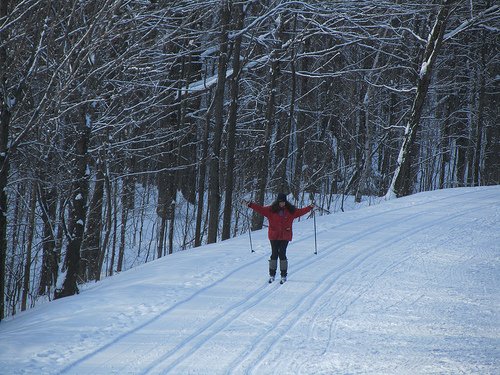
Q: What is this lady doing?
A: Skiing.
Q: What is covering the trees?
A: Snow.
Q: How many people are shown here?
A: One.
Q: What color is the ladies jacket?
A: Red.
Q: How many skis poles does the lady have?
A: Two.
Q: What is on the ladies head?
A: A hat.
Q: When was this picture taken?
A: In the daytime.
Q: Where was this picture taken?
A: On a snow filled forest trail.